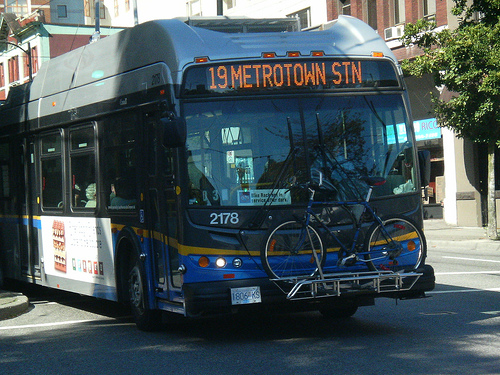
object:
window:
[99, 115, 143, 214]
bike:
[259, 181, 428, 288]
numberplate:
[231, 286, 262, 305]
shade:
[0, 282, 500, 375]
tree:
[397, 0, 500, 241]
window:
[66, 121, 99, 211]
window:
[38, 128, 65, 213]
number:
[209, 212, 239, 224]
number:
[209, 66, 228, 90]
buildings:
[0, 0, 327, 103]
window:
[181, 86, 420, 209]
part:
[220, 149, 268, 190]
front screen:
[182, 90, 420, 209]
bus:
[0, 13, 434, 333]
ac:
[383, 24, 405, 41]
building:
[326, 0, 498, 230]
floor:
[0, 247, 500, 375]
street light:
[0, 41, 33, 82]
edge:
[232, 299, 262, 306]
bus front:
[173, 13, 435, 322]